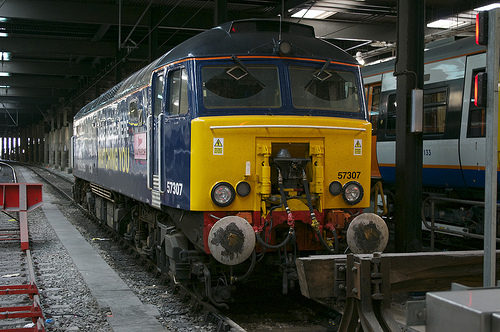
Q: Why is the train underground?
A: In the subway.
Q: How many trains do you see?
A: Two.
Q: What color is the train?
A: Yellow and blue.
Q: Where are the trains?
A: On the tracks.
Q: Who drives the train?
A: An engineer.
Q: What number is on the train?
A: 57307.